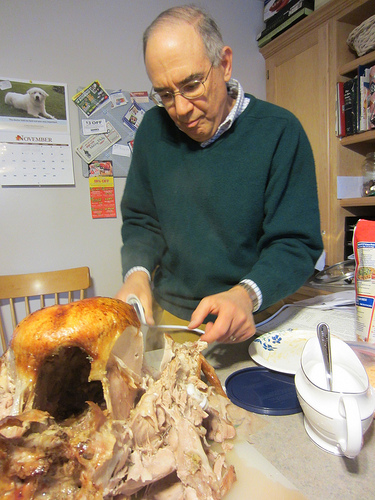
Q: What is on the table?
A: A turkey.